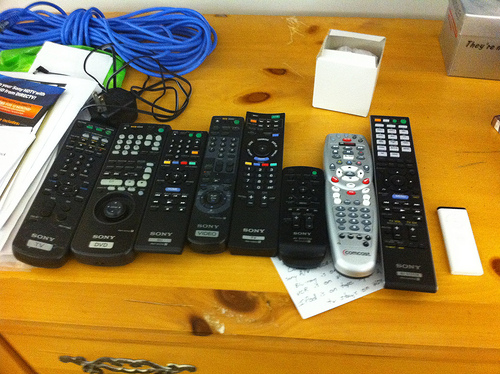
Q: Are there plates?
A: No, there are no plates.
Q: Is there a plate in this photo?
A: No, there are no plates.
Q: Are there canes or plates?
A: No, there are no plates or canes.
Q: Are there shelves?
A: No, there are no shelves.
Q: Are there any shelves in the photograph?
A: No, there are no shelves.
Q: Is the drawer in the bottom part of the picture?
A: Yes, the drawer is in the bottom of the image.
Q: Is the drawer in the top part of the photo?
A: No, the drawer is in the bottom of the image.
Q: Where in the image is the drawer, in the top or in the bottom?
A: The drawer is in the bottom of the image.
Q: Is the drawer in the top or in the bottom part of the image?
A: The drawer is in the bottom of the image.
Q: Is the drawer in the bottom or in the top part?
A: The drawer is in the bottom of the image.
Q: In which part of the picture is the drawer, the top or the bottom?
A: The drawer is in the bottom of the image.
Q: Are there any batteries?
A: No, there are no batteries.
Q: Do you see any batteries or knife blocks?
A: No, there are no batteries or knife blocks.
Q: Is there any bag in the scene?
A: Yes, there is a bag.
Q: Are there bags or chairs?
A: Yes, there is a bag.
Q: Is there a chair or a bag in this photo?
A: Yes, there is a bag.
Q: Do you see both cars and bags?
A: No, there is a bag but no cars.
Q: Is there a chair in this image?
A: No, there are no chairs.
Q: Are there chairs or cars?
A: No, there are no chairs or cars.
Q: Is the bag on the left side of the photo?
A: Yes, the bag is on the left of the image.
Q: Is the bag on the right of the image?
A: No, the bag is on the left of the image.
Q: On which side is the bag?
A: The bag is on the left of the image.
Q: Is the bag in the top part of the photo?
A: Yes, the bag is in the top of the image.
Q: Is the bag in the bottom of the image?
A: No, the bag is in the top of the image.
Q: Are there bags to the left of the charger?
A: Yes, there is a bag to the left of the charger.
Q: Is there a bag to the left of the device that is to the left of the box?
A: Yes, there is a bag to the left of the charger.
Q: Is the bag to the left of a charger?
A: Yes, the bag is to the left of a charger.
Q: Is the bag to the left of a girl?
A: No, the bag is to the left of a charger.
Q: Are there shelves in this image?
A: No, there are no shelves.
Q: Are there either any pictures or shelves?
A: No, there are no shelves or pictures.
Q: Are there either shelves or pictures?
A: No, there are no shelves or pictures.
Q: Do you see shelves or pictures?
A: No, there are no shelves or pictures.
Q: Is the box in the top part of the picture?
A: Yes, the box is in the top of the image.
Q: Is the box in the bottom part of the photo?
A: No, the box is in the top of the image.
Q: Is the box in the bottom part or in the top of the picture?
A: The box is in the top of the image.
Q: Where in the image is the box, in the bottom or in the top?
A: The box is in the top of the image.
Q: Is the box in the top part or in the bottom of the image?
A: The box is in the top of the image.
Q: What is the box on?
A: The box is on the table.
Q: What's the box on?
A: The box is on the table.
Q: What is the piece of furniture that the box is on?
A: The piece of furniture is a table.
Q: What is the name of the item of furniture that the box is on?
A: The piece of furniture is a table.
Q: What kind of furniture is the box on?
A: The box is on the table.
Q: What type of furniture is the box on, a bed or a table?
A: The box is on a table.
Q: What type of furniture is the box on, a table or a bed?
A: The box is on a table.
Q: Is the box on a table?
A: Yes, the box is on a table.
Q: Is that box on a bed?
A: No, the box is on a table.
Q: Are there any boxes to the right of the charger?
A: Yes, there is a box to the right of the charger.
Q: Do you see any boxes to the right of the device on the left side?
A: Yes, there is a box to the right of the charger.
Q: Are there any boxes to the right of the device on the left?
A: Yes, there is a box to the right of the charger.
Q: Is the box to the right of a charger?
A: Yes, the box is to the right of a charger.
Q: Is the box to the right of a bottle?
A: No, the box is to the right of a charger.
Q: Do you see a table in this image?
A: Yes, there is a table.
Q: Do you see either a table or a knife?
A: Yes, there is a table.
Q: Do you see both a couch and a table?
A: No, there is a table but no couches.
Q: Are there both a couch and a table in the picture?
A: No, there is a table but no couches.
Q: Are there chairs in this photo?
A: No, there are no chairs.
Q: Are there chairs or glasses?
A: No, there are no chairs or glasses.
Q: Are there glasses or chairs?
A: No, there are no chairs or glasses.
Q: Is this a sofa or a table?
A: This is a table.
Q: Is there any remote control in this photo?
A: Yes, there is a remote control.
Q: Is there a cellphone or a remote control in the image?
A: Yes, there is a remote control.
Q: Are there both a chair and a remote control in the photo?
A: No, there is a remote control but no chairs.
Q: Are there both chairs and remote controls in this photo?
A: No, there is a remote control but no chairs.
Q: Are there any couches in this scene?
A: No, there are no couches.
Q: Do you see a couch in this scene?
A: No, there are no couches.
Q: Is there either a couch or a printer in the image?
A: No, there are no couches or printers.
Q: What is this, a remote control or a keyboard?
A: This is a remote control.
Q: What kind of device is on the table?
A: The device is a remote control.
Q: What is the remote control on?
A: The remote control is on the table.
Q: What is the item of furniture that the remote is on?
A: The piece of furniture is a table.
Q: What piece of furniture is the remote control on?
A: The remote is on the table.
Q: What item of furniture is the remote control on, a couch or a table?
A: The remote control is on a table.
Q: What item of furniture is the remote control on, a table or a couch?
A: The remote control is on a table.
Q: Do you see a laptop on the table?
A: No, there is a remote control on the table.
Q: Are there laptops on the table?
A: No, there is a remote control on the table.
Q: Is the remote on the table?
A: Yes, the remote is on the table.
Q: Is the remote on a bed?
A: No, the remote is on the table.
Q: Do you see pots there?
A: No, there are no pots.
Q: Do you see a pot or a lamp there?
A: No, there are no pots or lamps.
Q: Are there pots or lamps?
A: No, there are no pots or lamps.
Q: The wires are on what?
A: The wires are on the table.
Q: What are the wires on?
A: The wires are on the table.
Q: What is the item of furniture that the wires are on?
A: The piece of furniture is a table.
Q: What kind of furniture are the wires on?
A: The wires are on the table.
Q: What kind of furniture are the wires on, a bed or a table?
A: The wires are on a table.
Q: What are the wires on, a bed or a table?
A: The wires are on a table.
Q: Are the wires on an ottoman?
A: No, the wires are on the table.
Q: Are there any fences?
A: No, there are no fences.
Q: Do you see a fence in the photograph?
A: No, there are no fences.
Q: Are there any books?
A: No, there are no books.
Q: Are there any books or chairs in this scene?
A: No, there are no books or chairs.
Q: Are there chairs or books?
A: No, there are no books or chairs.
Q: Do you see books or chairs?
A: No, there are no books or chairs.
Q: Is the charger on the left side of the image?
A: Yes, the charger is on the left of the image.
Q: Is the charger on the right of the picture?
A: No, the charger is on the left of the image.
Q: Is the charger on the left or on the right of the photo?
A: The charger is on the left of the image.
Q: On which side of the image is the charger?
A: The charger is on the left of the image.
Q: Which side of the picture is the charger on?
A: The charger is on the left of the image.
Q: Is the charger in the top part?
A: Yes, the charger is in the top of the image.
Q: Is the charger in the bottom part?
A: No, the charger is in the top of the image.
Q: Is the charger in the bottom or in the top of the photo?
A: The charger is in the top of the image.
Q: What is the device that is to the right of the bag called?
A: The device is a charger.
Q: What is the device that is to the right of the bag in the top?
A: The device is a charger.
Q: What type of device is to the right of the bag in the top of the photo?
A: The device is a charger.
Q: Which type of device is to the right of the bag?
A: The device is a charger.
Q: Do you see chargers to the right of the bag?
A: Yes, there is a charger to the right of the bag.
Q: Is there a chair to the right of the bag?
A: No, there is a charger to the right of the bag.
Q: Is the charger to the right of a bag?
A: Yes, the charger is to the right of a bag.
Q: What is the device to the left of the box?
A: The device is a charger.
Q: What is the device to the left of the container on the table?
A: The device is a charger.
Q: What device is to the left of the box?
A: The device is a charger.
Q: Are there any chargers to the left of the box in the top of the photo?
A: Yes, there is a charger to the left of the box.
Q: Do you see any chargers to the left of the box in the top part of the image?
A: Yes, there is a charger to the left of the box.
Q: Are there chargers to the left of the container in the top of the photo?
A: Yes, there is a charger to the left of the box.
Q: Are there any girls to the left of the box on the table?
A: No, there is a charger to the left of the box.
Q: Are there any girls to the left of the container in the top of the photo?
A: No, there is a charger to the left of the box.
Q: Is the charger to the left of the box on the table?
A: Yes, the charger is to the left of the box.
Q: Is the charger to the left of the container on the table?
A: Yes, the charger is to the left of the box.